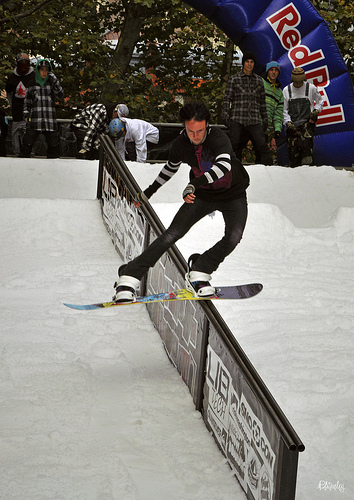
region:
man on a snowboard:
[50, 87, 292, 329]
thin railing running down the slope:
[87, 135, 339, 495]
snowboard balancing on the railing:
[53, 280, 271, 313]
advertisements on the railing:
[200, 333, 283, 493]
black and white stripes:
[198, 153, 232, 181]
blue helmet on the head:
[102, 114, 122, 135]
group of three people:
[220, 51, 329, 168]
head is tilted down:
[286, 64, 309, 89]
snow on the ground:
[1, 157, 353, 497]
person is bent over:
[64, 92, 134, 164]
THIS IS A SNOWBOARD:
[41, 266, 278, 318]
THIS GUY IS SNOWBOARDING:
[61, 95, 277, 314]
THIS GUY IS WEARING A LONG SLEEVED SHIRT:
[125, 122, 263, 205]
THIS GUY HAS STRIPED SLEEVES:
[135, 149, 233, 196]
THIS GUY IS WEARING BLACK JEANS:
[117, 186, 255, 274]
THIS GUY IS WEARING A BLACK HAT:
[231, 47, 258, 76]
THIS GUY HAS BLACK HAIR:
[170, 98, 213, 130]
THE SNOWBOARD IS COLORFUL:
[65, 282, 265, 308]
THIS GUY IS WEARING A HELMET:
[102, 113, 127, 143]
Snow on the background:
[55, 384, 189, 491]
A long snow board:
[52, 282, 279, 316]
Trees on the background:
[48, 12, 211, 95]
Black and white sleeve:
[181, 148, 238, 204]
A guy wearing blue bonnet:
[262, 57, 283, 88]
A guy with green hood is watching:
[28, 55, 61, 111]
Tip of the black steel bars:
[283, 420, 318, 459]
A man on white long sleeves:
[283, 69, 329, 128]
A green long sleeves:
[258, 80, 286, 136]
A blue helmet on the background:
[107, 117, 128, 135]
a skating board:
[57, 296, 217, 311]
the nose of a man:
[193, 130, 196, 137]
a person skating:
[147, 108, 251, 309]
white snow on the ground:
[11, 222, 111, 428]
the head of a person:
[178, 104, 212, 144]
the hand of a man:
[183, 176, 199, 207]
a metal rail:
[202, 307, 260, 373]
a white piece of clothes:
[125, 116, 150, 141]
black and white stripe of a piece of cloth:
[211, 153, 230, 187]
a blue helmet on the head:
[110, 120, 123, 133]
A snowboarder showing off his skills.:
[60, 87, 274, 318]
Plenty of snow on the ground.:
[37, 325, 138, 474]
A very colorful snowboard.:
[57, 276, 263, 319]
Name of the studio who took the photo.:
[313, 477, 347, 496]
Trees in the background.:
[97, 15, 198, 96]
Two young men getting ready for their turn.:
[69, 94, 168, 154]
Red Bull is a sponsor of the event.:
[268, 8, 347, 130]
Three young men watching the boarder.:
[219, 42, 322, 158]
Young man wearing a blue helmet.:
[109, 112, 122, 142]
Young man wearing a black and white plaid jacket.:
[20, 56, 68, 137]